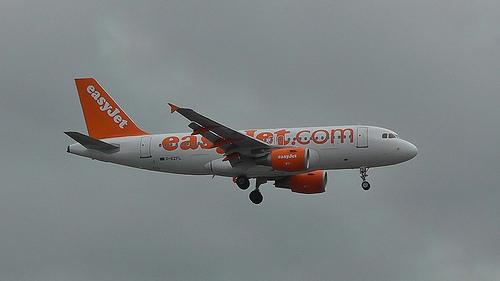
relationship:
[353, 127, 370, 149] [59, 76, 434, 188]
door on plane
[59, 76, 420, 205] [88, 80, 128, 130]
plane has tail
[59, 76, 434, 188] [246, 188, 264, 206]
plane has wheel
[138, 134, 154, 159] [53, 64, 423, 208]
door on plane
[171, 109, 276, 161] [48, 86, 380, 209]
wing on plane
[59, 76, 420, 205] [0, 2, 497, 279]
plane in sky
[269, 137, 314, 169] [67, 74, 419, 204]
turbine on plane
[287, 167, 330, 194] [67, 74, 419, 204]
turbine on plane